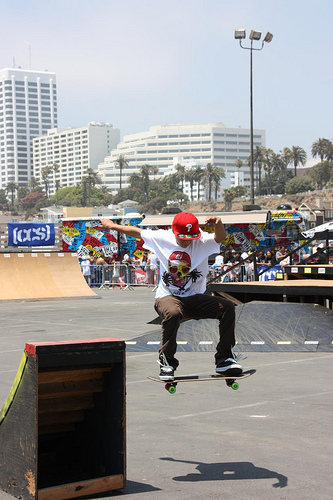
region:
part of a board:
[197, 373, 207, 389]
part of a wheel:
[235, 385, 240, 387]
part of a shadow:
[218, 463, 221, 468]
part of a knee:
[171, 333, 178, 347]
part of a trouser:
[170, 338, 172, 347]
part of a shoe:
[233, 361, 236, 367]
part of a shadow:
[229, 464, 232, 472]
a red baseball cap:
[173, 210, 204, 238]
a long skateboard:
[144, 367, 256, 390]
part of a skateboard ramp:
[0, 333, 141, 499]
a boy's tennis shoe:
[213, 356, 245, 374]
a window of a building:
[16, 80, 25, 85]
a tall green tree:
[275, 143, 307, 174]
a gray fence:
[103, 262, 129, 284]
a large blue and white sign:
[7, 223, 54, 245]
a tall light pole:
[229, 23, 273, 207]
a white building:
[29, 122, 118, 193]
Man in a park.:
[8, 188, 327, 494]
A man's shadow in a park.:
[155, 449, 291, 493]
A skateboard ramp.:
[0, 335, 145, 497]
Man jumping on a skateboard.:
[89, 204, 259, 394]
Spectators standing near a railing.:
[75, 239, 279, 277]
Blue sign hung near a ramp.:
[4, 220, 55, 247]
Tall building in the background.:
[0, 64, 63, 196]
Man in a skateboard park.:
[1, 209, 326, 497]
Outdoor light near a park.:
[229, 24, 273, 205]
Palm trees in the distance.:
[254, 135, 331, 192]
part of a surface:
[259, 437, 271, 465]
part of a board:
[183, 373, 188, 385]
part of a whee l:
[166, 378, 174, 397]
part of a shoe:
[230, 360, 232, 366]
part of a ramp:
[64, 411, 72, 424]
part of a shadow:
[220, 461, 229, 472]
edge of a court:
[223, 398, 232, 414]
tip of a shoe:
[234, 364, 243, 366]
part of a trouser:
[170, 358, 177, 361]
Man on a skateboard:
[128, 198, 259, 399]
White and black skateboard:
[142, 363, 263, 392]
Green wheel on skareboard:
[164, 386, 179, 394]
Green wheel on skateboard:
[229, 381, 243, 394]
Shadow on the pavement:
[152, 445, 298, 496]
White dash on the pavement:
[303, 329, 320, 350]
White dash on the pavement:
[277, 332, 291, 350]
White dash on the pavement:
[248, 331, 266, 350]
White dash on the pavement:
[195, 334, 215, 348]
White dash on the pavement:
[145, 336, 163, 350]